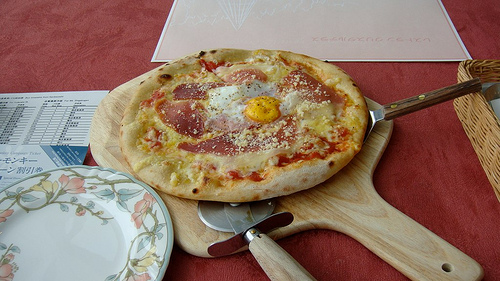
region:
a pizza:
[111, 51, 380, 200]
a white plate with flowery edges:
[1, 170, 164, 277]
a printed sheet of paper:
[3, 84, 97, 148]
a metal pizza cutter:
[188, 200, 332, 279]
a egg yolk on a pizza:
[241, 82, 292, 127]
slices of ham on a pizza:
[170, 81, 212, 144]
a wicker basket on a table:
[458, 58, 496, 194]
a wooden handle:
[381, 75, 490, 127]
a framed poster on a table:
[155, 0, 469, 57]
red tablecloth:
[25, 17, 120, 76]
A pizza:
[125, 35, 357, 203]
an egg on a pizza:
[201, 75, 309, 129]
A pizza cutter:
[188, 195, 287, 235]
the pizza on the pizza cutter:
[174, 160, 363, 277]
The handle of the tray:
[358, 185, 476, 277]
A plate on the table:
[5, 151, 158, 279]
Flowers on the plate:
[22, 180, 143, 278]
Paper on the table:
[0, 90, 86, 180]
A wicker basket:
[447, 57, 497, 191]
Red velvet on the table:
[38, 14, 118, 66]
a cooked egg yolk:
[235, 80, 300, 130]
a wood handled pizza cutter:
[193, 175, 326, 280]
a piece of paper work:
[1, 69, 107, 189]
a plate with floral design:
[6, 160, 179, 279]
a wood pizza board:
[95, 32, 497, 274]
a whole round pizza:
[123, 43, 383, 235]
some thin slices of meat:
[149, 72, 251, 183]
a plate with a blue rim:
[4, 162, 182, 271]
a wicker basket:
[429, 53, 498, 162]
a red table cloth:
[16, 11, 490, 255]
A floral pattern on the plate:
[124, 186, 168, 262]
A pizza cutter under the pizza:
[201, 196, 296, 276]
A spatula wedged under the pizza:
[353, 74, 485, 141]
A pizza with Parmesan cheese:
[133, 48, 367, 191]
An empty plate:
[7, 154, 167, 279]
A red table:
[42, 0, 143, 78]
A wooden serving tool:
[100, 60, 488, 276]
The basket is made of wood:
[457, 54, 499, 177]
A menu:
[0, 85, 99, 155]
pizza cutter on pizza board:
[193, 178, 328, 275]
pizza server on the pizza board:
[332, 80, 433, 142]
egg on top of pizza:
[201, 67, 307, 119]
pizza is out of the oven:
[152, 45, 372, 210]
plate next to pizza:
[30, 171, 157, 266]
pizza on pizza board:
[137, 47, 477, 258]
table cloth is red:
[27, 6, 107, 103]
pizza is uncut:
[113, 37, 352, 193]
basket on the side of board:
[449, 55, 497, 158]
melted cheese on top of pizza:
[197, 86, 359, 172]